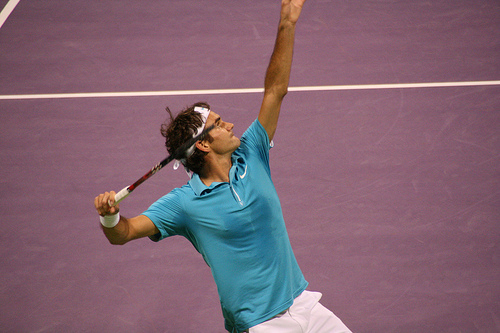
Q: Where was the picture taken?
A: Tennis court.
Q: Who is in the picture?
A: A man.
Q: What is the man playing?
A: Tennis.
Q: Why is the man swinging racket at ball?
A: To serve it.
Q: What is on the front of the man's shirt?
A: Sweat.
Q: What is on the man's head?
A: A headband.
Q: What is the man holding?
A: A racket.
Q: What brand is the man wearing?
A: Nike.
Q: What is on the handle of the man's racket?
A: Tape.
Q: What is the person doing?
A: Playing a sport.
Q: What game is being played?
A: Tennis.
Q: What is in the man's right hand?
A: Tennis racquet.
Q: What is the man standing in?
A: Tennis court.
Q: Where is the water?
A: No water.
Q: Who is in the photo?
A: A man.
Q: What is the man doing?
A: Playing tennis.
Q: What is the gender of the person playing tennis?
A: Male.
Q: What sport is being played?
A: Tennis.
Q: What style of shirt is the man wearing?
A: Polo shirt.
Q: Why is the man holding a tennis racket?
A: He is playing tennis.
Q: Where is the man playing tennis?
A: Tennis court.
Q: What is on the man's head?
A: Headband.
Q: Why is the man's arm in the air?
A: He is serving the tennis ball.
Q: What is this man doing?
A: Playing tennis.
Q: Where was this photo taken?
A: A tennis court.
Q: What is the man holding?
A: A tennis racket.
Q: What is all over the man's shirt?
A: Sweat.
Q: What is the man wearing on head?
A: A headband.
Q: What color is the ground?
A: Purple.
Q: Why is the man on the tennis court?
A: Playing tennis.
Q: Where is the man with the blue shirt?
A: Tennis court.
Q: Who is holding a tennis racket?
A: The man.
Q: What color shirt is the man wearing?
A: Blue.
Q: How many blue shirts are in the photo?
A: One.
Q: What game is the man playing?
A: Tennis.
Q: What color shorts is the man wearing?
A: White.